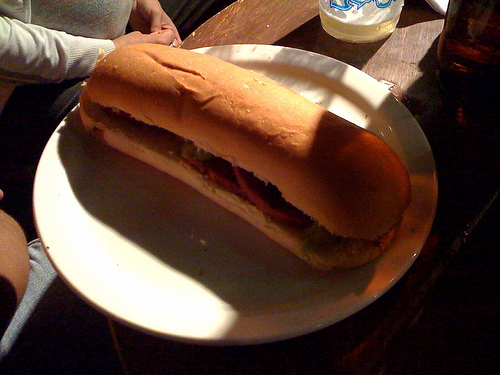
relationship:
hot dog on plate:
[88, 95, 344, 257] [306, 68, 362, 107]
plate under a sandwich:
[29, 37, 444, 349] [76, 39, 415, 277]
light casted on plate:
[29, 161, 115, 325] [29, 37, 444, 349]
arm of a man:
[0, 15, 116, 90] [0, 1, 186, 211]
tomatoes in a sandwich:
[145, 91, 333, 246] [59, 37, 444, 239]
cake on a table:
[320, 0, 401, 46] [169, 0, 496, 370]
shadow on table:
[394, 74, 489, 259] [344, 9, 492, 301]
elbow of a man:
[0, 194, 30, 314] [3, 227, 95, 354]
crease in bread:
[142, 47, 208, 79] [74, 38, 415, 275]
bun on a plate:
[75, 42, 409, 270] [28, 133, 354, 342]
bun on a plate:
[75, 42, 409, 270] [29, 37, 444, 349]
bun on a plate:
[75, 42, 409, 270] [46, 20, 461, 357]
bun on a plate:
[88, 42, 416, 241] [29, 37, 444, 349]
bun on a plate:
[75, 42, 409, 270] [40, 25, 446, 324]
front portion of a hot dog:
[232, 66, 427, 278] [88, 95, 344, 257]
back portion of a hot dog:
[78, 40, 193, 175] [76, 15, 421, 283]